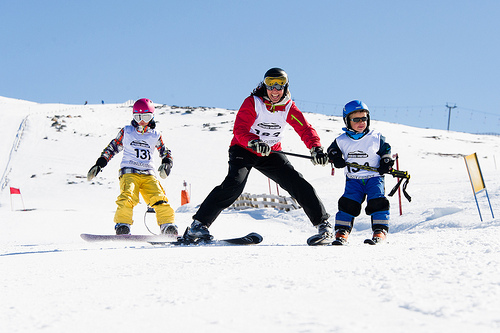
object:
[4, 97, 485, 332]
ground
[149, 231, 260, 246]
board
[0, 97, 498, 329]
snow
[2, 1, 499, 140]
sky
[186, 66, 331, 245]
woman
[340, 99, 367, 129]
helmet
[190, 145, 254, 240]
legs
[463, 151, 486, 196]
sign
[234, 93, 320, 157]
jacket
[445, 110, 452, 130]
post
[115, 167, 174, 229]
pants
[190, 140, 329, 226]
pants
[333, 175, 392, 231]
pants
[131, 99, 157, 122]
helmet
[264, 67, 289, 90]
helmet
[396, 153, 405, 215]
pole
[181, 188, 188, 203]
cone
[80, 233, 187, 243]
skis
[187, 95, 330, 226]
snowsuits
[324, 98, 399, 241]
boy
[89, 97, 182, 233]
girl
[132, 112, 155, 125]
goggles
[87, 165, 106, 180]
gloves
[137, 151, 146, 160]
numbers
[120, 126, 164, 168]
chest